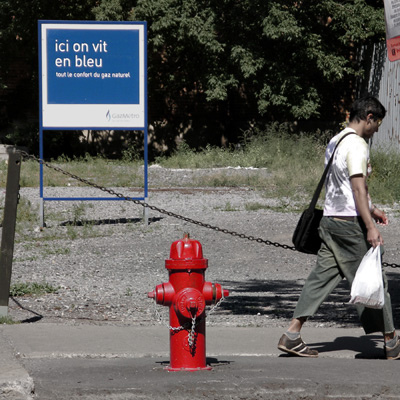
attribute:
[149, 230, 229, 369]
fire hydrant — red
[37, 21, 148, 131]
sign — blue, white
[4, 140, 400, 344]
fence — chain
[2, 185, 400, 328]
driveway — stone gravel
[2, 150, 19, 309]
post — metal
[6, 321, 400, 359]
sidewalk — concrete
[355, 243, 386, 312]
grocery bag — white, plastic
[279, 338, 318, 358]
sneaker — brown, white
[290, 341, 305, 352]
stripes — white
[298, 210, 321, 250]
bag — black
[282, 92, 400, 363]
man — walking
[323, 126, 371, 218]
shirt — white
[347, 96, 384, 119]
hair — dark